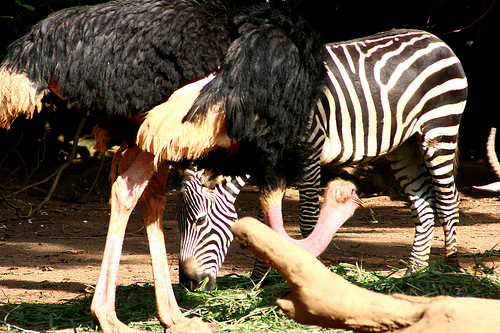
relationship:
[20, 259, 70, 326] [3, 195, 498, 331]
shadow on ground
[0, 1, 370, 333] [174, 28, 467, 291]
bird next to animal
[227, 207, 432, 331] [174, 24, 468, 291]
trunk next to animal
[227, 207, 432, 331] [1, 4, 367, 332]
trunk next to animal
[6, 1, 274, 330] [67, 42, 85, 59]
bird has feather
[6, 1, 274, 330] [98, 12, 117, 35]
bird has feather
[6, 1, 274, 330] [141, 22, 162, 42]
bird has feather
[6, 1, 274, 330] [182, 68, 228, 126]
bird has feather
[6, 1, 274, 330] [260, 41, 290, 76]
bird has feather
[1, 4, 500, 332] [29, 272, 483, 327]
animal standing on grass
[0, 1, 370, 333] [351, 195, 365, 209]
bird has nose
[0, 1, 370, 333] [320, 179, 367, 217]
bird has head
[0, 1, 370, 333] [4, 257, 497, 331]
bird standing on grass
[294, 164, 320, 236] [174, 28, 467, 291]
leg of animal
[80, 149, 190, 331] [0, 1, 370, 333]
legs of bird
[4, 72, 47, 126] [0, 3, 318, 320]
fur of ostrich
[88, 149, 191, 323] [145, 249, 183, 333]
legs of ostrichs leg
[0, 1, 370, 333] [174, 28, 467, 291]
bird and a animal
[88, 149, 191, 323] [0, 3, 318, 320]
legs right side of ostrich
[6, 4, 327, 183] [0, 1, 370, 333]
feathers of bird